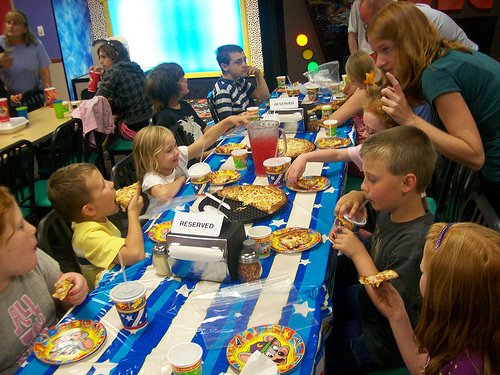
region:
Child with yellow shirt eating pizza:
[40, 163, 151, 268]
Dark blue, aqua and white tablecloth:
[248, 257, 333, 324]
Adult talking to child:
[362, 3, 497, 198]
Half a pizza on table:
[205, 175, 285, 215]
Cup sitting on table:
[256, 155, 291, 190]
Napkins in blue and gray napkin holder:
[150, 225, 240, 290]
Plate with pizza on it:
[216, 320, 311, 370]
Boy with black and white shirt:
[205, 41, 271, 111]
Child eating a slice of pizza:
[362, 220, 491, 364]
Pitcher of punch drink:
[242, 118, 283, 178]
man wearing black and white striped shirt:
[203, 42, 260, 115]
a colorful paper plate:
[232, 305, 317, 372]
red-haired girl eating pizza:
[362, 217, 497, 368]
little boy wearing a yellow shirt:
[54, 158, 155, 265]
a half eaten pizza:
[209, 176, 289, 226]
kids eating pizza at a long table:
[7, 120, 487, 347]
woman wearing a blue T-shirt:
[1, 5, 76, 100]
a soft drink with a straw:
[37, 76, 57, 101]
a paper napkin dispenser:
[165, 215, 240, 280]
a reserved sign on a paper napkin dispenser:
[166, 203, 236, 236]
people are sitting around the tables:
[0, 1, 495, 361]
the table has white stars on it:
[93, 159, 328, 373]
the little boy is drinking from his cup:
[333, 112, 438, 332]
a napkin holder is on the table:
[155, 204, 259, 308]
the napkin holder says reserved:
[153, 207, 274, 319]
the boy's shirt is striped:
[198, 31, 259, 127]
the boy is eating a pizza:
[52, 157, 157, 284]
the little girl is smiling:
[133, 127, 210, 206]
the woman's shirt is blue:
[3, 3, 63, 100]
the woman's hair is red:
[368, 12, 498, 178]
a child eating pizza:
[37, 160, 147, 287]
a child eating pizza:
[355, 219, 498, 371]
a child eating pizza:
[0, 180, 87, 372]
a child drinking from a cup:
[325, 123, 431, 310]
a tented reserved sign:
[170, 207, 230, 237]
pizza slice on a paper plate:
[267, 221, 320, 258]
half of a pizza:
[198, 180, 285, 227]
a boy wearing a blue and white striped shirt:
[202, 40, 272, 123]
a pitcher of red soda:
[242, 115, 287, 177]